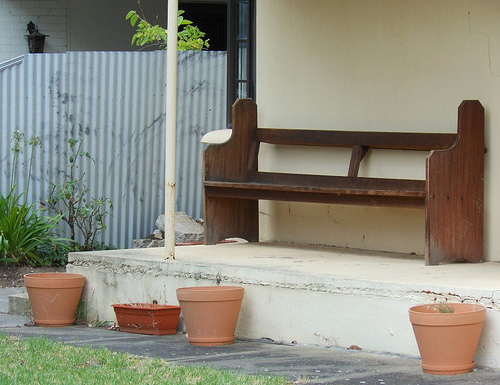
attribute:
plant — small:
[54, 178, 107, 270]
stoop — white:
[72, 261, 131, 349]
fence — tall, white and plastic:
[44, 63, 184, 153]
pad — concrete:
[267, 235, 394, 327]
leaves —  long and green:
[28, 149, 97, 229]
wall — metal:
[87, 102, 193, 213]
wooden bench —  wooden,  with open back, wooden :
[188, 98, 487, 263]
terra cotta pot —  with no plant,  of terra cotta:
[20, 270, 85, 329]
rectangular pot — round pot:
[108, 295, 184, 341]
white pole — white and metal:
[153, 3, 187, 258]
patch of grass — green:
[3, 317, 288, 384]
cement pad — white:
[65, 221, 500, 325]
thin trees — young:
[8, 125, 41, 208]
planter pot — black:
[21, 25, 52, 56]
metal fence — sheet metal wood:
[0, 45, 232, 250]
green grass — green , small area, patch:
[2, 328, 290, 383]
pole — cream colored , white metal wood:
[156, 3, 185, 261]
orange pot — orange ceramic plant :
[411, 295, 486, 373]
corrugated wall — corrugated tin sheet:
[3, 44, 239, 239]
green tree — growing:
[42, 133, 122, 243]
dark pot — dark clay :
[106, 296, 181, 346]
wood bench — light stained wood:
[197, 90, 488, 274]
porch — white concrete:
[65, 234, 498, 364]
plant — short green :
[2, 185, 61, 267]